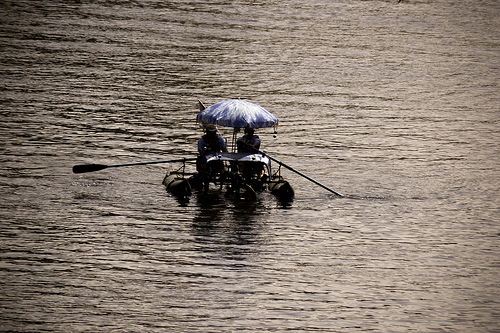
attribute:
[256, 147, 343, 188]
oar — long, wooden, thin, angled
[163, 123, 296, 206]
boat — make shift, floating, cylinders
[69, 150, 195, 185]
oar — long, wooden, thin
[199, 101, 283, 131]
umbrella — blue, big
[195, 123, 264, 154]
people — rowing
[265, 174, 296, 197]
cylinder — floating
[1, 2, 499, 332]
water — ripply, gray, calm, still, dark, sunlit, black, dark grey